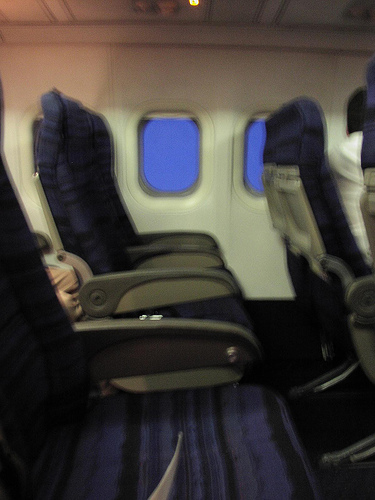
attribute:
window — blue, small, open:
[138, 111, 203, 196]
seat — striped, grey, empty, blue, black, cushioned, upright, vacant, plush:
[26, 87, 255, 329]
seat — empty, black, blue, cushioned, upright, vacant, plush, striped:
[0, 149, 321, 500]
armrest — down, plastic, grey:
[80, 262, 242, 320]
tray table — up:
[273, 167, 330, 279]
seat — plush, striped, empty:
[273, 95, 370, 386]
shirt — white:
[328, 131, 371, 269]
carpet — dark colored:
[240, 297, 374, 498]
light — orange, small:
[187, 0, 201, 8]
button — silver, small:
[223, 346, 241, 367]